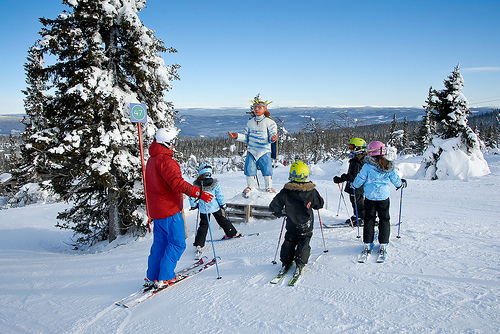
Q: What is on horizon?
A: Blue valley.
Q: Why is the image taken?
A: Remembrance.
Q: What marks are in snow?
A: Ski marks.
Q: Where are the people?
A: On a ski slope.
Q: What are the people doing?
A: Skiing.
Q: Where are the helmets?
A: ON the people's heads.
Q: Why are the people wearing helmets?
A: Safety.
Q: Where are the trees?
A: Beside the people.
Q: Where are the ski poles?
A: In the people's hands.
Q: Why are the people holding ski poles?
A: Balance.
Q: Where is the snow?
A: On the ground.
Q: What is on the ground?
A: Snow.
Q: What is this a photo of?
A: People skiing.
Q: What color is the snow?
A: White.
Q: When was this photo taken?
A: In the daytime.